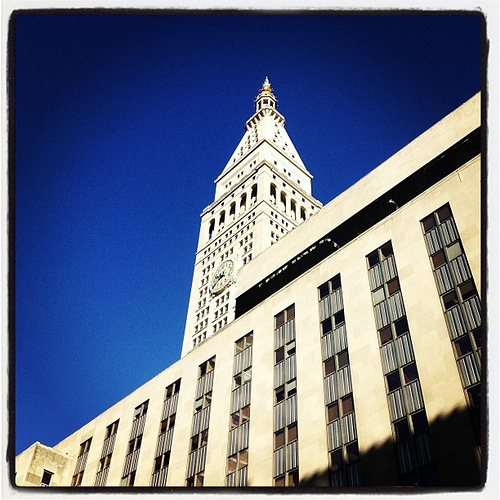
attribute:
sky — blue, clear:
[19, 32, 201, 211]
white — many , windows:
[17, 71, 487, 489]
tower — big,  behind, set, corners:
[179, 72, 339, 366]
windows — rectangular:
[312, 261, 359, 492]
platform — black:
[234, 89, 486, 324]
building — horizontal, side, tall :
[34, 80, 469, 486]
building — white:
[79, 189, 422, 439]